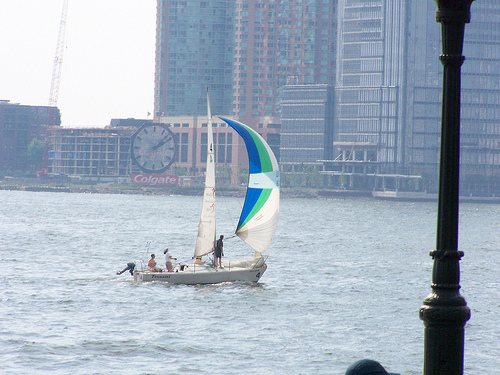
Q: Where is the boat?
A: On the water.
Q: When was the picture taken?
A: Daytime.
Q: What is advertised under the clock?
A: Colgate.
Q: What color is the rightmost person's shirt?
A: Black.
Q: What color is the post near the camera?
A: Black.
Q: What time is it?
A: 3:10.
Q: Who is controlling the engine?
A: The man in pink.